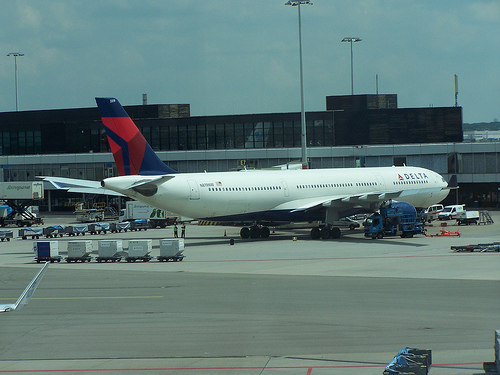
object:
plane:
[36, 95, 461, 238]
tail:
[35, 96, 179, 216]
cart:
[156, 238, 188, 262]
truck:
[361, 201, 424, 240]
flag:
[216, 179, 225, 187]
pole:
[283, 0, 316, 166]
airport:
[0, 93, 500, 213]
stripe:
[2, 360, 494, 374]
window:
[323, 116, 336, 144]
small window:
[296, 182, 299, 190]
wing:
[275, 188, 408, 213]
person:
[173, 222, 179, 240]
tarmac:
[2, 210, 499, 374]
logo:
[395, 172, 431, 178]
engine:
[323, 194, 396, 218]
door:
[186, 173, 201, 201]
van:
[437, 202, 467, 218]